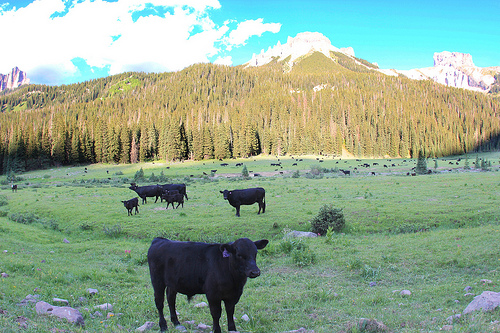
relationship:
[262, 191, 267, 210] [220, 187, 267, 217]
tail on a body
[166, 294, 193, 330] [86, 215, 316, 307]
leg of cow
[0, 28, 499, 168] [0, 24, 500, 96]
mountain top in distance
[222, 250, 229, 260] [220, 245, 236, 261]
tag on ear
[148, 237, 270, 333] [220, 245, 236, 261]
black cattle has ear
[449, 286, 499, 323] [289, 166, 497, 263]
rock in field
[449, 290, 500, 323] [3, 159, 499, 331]
rock in field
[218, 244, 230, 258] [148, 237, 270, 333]
ear on black cattle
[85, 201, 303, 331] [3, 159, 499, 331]
cow in field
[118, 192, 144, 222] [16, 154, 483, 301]
cow in field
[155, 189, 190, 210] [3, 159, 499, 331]
black cow in field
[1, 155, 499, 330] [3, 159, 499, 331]
cows in field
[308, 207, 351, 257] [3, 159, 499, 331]
bush in field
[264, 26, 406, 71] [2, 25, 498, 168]
snow on mountain top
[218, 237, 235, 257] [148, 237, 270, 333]
ear of black cattle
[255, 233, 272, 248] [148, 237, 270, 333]
ear of black cattle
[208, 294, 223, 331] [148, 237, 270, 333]
leg of black cattle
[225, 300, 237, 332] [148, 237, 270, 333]
leg of black cattle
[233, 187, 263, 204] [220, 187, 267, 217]
body of body